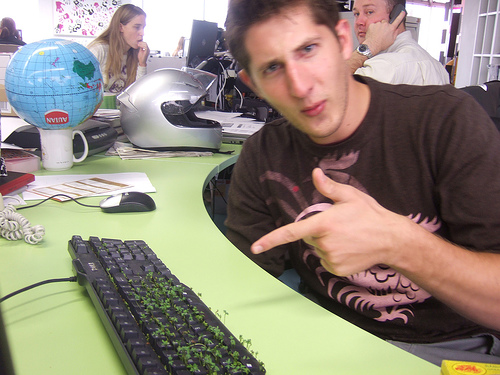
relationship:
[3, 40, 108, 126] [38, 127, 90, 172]
globe on mug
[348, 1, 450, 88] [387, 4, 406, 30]
man holding phone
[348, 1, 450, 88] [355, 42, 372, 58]
man wearing a watch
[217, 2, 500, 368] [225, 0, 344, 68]
man has short hair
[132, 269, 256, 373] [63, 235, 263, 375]
grass on keyboard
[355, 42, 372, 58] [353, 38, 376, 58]
watch on wrist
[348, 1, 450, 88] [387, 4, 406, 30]
man on phone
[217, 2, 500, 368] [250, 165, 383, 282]
man has a hand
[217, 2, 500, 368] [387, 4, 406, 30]
man holding phone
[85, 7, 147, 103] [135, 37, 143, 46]
woman has hand on her mouth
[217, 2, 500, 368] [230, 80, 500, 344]
man has a brown shirt